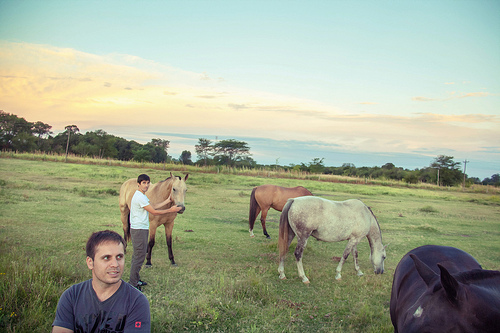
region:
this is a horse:
[272, 191, 392, 305]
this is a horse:
[369, 245, 498, 330]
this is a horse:
[237, 159, 311, 239]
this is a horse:
[100, 148, 223, 300]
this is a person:
[43, 227, 180, 327]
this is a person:
[110, 161, 172, 307]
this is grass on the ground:
[178, 268, 243, 315]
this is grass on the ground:
[214, 248, 262, 308]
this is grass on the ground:
[21, 217, 68, 274]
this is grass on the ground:
[195, 267, 270, 324]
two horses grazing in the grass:
[232, 163, 397, 299]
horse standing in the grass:
[111, 168, 193, 268]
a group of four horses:
[99, 150, 497, 330]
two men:
[55, 170, 184, 330]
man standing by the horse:
[119, 166, 204, 284]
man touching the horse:
[101, 156, 201, 298]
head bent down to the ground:
[366, 235, 391, 279]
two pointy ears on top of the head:
[405, 250, 472, 309]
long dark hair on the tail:
[243, 183, 260, 230]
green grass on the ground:
[1, 150, 498, 330]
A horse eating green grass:
[270, 195, 385, 281]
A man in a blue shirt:
[50, 225, 150, 325]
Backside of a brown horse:
[245, 180, 270, 240]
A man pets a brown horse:
[117, 171, 187, 283]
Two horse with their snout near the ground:
[246, 181, 382, 276]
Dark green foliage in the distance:
[0, 110, 170, 157]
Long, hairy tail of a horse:
[275, 195, 285, 260]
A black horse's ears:
[405, 246, 465, 301]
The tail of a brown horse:
[245, 185, 255, 230]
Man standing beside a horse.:
[125, 167, 151, 285]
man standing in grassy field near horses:
[43, 227, 160, 331]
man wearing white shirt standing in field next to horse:
[118, 171, 183, 293]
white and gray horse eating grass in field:
[273, 192, 389, 287]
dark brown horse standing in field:
[378, 241, 498, 331]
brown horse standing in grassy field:
[246, 183, 326, 242]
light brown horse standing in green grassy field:
[115, 169, 192, 268]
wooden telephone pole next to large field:
[458, 157, 470, 187]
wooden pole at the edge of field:
[61, 121, 75, 162]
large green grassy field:
[0, 148, 499, 332]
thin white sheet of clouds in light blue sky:
[0, 40, 498, 158]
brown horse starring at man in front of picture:
[386, 231, 499, 326]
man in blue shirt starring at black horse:
[51, 228, 160, 330]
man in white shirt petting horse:
[125, 170, 184, 289]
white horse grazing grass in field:
[273, 191, 389, 286]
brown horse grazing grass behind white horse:
[237, 180, 310, 241]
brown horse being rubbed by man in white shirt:
[117, 168, 192, 268]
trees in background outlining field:
[0, 102, 499, 194]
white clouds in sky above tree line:
[0, 40, 499, 166]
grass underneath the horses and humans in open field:
[0, 143, 499, 332]